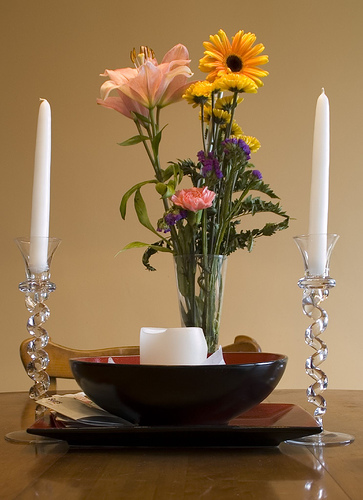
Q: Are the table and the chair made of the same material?
A: Yes, both the table and the chair are made of wood.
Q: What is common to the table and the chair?
A: The material, both the table and the chair are wooden.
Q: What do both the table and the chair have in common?
A: The material, both the table and the chair are wooden.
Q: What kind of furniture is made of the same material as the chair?
A: The table is made of the same material as the chair.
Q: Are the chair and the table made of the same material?
A: Yes, both the chair and the table are made of wood.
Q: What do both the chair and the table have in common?
A: The material, both the chair and the table are wooden.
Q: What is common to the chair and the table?
A: The material, both the chair and the table are wooden.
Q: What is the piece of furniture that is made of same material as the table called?
A: The piece of furniture is a chair.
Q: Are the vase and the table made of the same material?
A: No, the vase is made of glass and the table is made of wood.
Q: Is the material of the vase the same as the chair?
A: No, the vase is made of glass and the chair is made of wood.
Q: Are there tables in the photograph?
A: Yes, there is a table.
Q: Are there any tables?
A: Yes, there is a table.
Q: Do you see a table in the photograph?
A: Yes, there is a table.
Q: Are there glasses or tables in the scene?
A: Yes, there is a table.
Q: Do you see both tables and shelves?
A: No, there is a table but no shelves.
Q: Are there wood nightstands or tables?
A: Yes, there is a wood table.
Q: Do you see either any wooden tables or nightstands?
A: Yes, there is a wood table.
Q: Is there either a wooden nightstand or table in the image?
A: Yes, there is a wood table.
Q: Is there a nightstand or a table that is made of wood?
A: Yes, the table is made of wood.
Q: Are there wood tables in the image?
A: Yes, there is a wood table.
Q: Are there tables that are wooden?
A: Yes, there is a table that is wooden.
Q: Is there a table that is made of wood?
A: Yes, there is a table that is made of wood.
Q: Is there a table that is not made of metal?
A: Yes, there is a table that is made of wood.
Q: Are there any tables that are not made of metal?
A: Yes, there is a table that is made of wood.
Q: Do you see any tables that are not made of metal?
A: Yes, there is a table that is made of wood.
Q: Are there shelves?
A: No, there are no shelves.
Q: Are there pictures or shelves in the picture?
A: No, there are no shelves or pictures.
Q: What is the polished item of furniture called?
A: The piece of furniture is a table.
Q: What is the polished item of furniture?
A: The piece of furniture is a table.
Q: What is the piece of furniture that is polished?
A: The piece of furniture is a table.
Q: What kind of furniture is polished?
A: The furniture is a table.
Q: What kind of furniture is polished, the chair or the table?
A: The table is polished.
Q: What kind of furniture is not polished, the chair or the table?
A: The chair is not polished.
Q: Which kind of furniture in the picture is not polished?
A: The furniture is a chair.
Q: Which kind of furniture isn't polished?
A: The furniture is a chair.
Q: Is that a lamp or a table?
A: That is a table.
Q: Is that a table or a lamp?
A: That is a table.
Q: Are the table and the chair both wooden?
A: Yes, both the table and the chair are wooden.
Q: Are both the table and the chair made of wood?
A: Yes, both the table and the chair are made of wood.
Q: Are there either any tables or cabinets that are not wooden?
A: No, there is a table but it is wooden.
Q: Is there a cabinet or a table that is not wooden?
A: No, there is a table but it is wooden.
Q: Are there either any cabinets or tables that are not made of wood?
A: No, there is a table but it is made of wood.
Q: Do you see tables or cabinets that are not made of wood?
A: No, there is a table but it is made of wood.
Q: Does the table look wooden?
A: Yes, the table is wooden.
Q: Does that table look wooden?
A: Yes, the table is wooden.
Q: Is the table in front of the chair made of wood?
A: Yes, the table is made of wood.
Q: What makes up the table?
A: The table is made of wood.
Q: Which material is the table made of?
A: The table is made of wood.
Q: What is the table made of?
A: The table is made of wood.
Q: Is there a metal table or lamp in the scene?
A: No, there is a table but it is wooden.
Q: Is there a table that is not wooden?
A: No, there is a table but it is wooden.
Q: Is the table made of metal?
A: No, the table is made of wood.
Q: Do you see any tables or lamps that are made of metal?
A: No, there is a table but it is made of wood.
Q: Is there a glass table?
A: No, there is a table but it is made of wood.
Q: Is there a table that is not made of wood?
A: No, there is a table but it is made of wood.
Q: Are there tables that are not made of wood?
A: No, there is a table but it is made of wood.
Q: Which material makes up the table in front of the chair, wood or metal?
A: The table is made of wood.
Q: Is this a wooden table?
A: Yes, this is a wooden table.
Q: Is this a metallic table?
A: No, this is a wooden table.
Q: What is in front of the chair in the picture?
A: The table is in front of the chair.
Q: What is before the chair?
A: The table is in front of the chair.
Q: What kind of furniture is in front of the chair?
A: The piece of furniture is a table.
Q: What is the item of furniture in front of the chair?
A: The piece of furniture is a table.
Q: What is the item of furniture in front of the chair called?
A: The piece of furniture is a table.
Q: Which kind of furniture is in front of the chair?
A: The piece of furniture is a table.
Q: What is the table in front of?
A: The table is in front of the chair.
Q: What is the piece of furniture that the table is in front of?
A: The piece of furniture is a chair.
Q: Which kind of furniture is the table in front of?
A: The table is in front of the chair.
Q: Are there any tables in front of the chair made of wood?
A: Yes, there is a table in front of the chair.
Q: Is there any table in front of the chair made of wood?
A: Yes, there is a table in front of the chair.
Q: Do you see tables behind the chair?
A: No, the table is in front of the chair.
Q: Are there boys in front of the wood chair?
A: No, there is a table in front of the chair.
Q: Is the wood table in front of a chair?
A: Yes, the table is in front of a chair.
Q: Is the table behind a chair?
A: No, the table is in front of a chair.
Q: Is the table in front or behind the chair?
A: The table is in front of the chair.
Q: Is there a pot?
A: No, there are no pots.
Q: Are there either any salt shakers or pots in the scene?
A: No, there are no pots or salt shakers.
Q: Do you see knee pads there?
A: No, there are no knee pads.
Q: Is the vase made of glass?
A: Yes, the vase is made of glass.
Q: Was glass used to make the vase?
A: Yes, the vase is made of glass.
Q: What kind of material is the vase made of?
A: The vase is made of glass.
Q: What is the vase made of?
A: The vase is made of glass.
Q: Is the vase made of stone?
A: No, the vase is made of glass.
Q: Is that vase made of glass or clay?
A: The vase is made of glass.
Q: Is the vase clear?
A: Yes, the vase is clear.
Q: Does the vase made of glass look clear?
A: Yes, the vase is clear.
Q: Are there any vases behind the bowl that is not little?
A: Yes, there is a vase behind the bowl.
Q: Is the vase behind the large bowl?
A: Yes, the vase is behind the bowl.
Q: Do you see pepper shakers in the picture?
A: No, there are no pepper shakers.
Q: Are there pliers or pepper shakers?
A: No, there are no pepper shakers or pliers.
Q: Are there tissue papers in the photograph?
A: No, there are no tissue papers.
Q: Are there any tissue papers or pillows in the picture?
A: No, there are no tissue papers or pillows.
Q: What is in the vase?
A: The flower is in the vase.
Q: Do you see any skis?
A: No, there are no skis.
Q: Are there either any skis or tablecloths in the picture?
A: No, there are no skis or tablecloths.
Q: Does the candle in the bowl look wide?
A: Yes, the candle is wide.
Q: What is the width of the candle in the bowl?
A: The candle is wide.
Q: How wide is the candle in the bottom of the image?
A: The candle is wide.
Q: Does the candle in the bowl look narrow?
A: No, the candle is wide.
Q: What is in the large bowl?
A: The candle is in the bowl.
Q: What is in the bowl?
A: The candle is in the bowl.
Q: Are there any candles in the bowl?
A: Yes, there is a candle in the bowl.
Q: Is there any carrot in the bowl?
A: No, there is a candle in the bowl.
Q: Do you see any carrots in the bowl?
A: No, there is a candle in the bowl.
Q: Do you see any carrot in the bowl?
A: No, there is a candle in the bowl.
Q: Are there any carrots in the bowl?
A: No, there is a candle in the bowl.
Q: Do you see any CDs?
A: No, there are no cds.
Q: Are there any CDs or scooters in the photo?
A: No, there are no CDs or scooters.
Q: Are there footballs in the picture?
A: No, there are no footballs.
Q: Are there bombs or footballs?
A: No, there are no footballs or bombs.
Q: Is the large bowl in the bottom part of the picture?
A: Yes, the bowl is in the bottom of the image.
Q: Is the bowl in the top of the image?
A: No, the bowl is in the bottom of the image.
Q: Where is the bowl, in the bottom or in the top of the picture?
A: The bowl is in the bottom of the image.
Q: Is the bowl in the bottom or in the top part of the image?
A: The bowl is in the bottom of the image.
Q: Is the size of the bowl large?
A: Yes, the bowl is large.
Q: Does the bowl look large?
A: Yes, the bowl is large.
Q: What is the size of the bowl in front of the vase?
A: The bowl is large.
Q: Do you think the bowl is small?
A: No, the bowl is large.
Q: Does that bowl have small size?
A: No, the bowl is large.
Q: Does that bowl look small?
A: No, the bowl is large.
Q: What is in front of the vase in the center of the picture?
A: The bowl is in front of the vase.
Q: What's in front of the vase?
A: The bowl is in front of the vase.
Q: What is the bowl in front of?
A: The bowl is in front of the vase.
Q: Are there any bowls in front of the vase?
A: Yes, there is a bowl in front of the vase.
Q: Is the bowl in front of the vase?
A: Yes, the bowl is in front of the vase.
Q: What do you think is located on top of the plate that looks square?
A: The bowl is on top of the plate.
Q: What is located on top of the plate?
A: The bowl is on top of the plate.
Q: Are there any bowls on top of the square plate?
A: Yes, there is a bowl on top of the plate.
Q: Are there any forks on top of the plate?
A: No, there is a bowl on top of the plate.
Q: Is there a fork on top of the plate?
A: No, there is a bowl on top of the plate.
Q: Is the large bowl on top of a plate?
A: Yes, the bowl is on top of a plate.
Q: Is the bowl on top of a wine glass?
A: No, the bowl is on top of a plate.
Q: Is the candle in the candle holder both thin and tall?
A: No, the candle is tall but thick.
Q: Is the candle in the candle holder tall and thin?
A: No, the candle is tall but thick.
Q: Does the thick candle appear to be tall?
A: Yes, the candle is tall.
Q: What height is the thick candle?
A: The candle is tall.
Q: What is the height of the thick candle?
A: The candle is tall.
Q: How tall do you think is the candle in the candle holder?
A: The candle is tall.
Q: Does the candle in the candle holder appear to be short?
A: No, the candle is tall.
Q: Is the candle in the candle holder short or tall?
A: The candle is tall.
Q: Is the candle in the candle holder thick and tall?
A: Yes, the candle is thick and tall.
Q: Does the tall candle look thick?
A: Yes, the candle is thick.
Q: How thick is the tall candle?
A: The candle is thick.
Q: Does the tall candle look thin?
A: No, the candle is thick.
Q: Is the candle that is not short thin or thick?
A: The candle is thick.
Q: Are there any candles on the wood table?
A: Yes, there is a candle on the table.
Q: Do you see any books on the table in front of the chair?
A: No, there is a candle on the table.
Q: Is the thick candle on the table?
A: Yes, the candle is on the table.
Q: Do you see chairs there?
A: Yes, there is a chair.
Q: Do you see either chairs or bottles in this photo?
A: Yes, there is a chair.